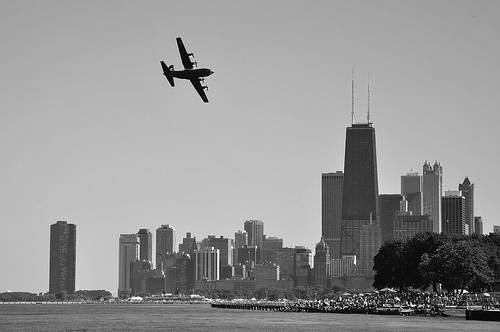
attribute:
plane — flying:
[159, 35, 222, 107]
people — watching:
[318, 284, 482, 313]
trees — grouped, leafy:
[375, 229, 499, 298]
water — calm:
[3, 305, 499, 331]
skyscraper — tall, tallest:
[342, 121, 381, 288]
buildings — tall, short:
[38, 164, 500, 291]